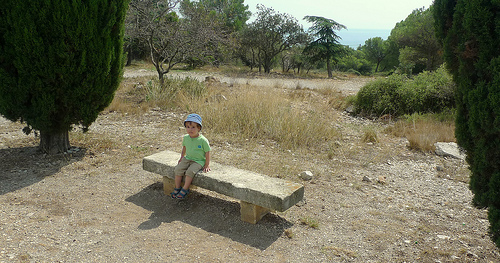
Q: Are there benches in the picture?
A: Yes, there is a bench.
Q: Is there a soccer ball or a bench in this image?
A: Yes, there is a bench.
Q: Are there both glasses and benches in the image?
A: No, there is a bench but no glasses.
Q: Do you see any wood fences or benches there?
A: Yes, there is a wood bench.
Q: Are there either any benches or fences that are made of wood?
A: Yes, the bench is made of wood.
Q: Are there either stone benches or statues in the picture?
A: Yes, there is a stone bench.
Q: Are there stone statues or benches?
A: Yes, there is a stone bench.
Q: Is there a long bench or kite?
A: Yes, there is a long bench.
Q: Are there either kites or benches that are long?
A: Yes, the bench is long.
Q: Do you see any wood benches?
A: Yes, there is a wood bench.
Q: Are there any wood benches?
A: Yes, there is a wood bench.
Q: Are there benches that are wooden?
A: Yes, there is a bench that is wooden.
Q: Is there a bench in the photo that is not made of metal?
A: Yes, there is a bench that is made of wood.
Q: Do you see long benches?
A: Yes, there is a long bench.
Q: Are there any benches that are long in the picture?
A: Yes, there is a long bench.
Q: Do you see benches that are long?
A: Yes, there is a bench that is long.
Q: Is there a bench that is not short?
A: Yes, there is a long bench.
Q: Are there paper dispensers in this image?
A: No, there are no paper dispensers.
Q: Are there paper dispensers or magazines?
A: No, there are no paper dispensers or magazines.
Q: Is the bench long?
A: Yes, the bench is long.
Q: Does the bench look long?
A: Yes, the bench is long.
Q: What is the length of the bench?
A: The bench is long.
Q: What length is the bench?
A: The bench is long.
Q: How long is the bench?
A: The bench is long.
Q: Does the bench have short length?
A: No, the bench is long.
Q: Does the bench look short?
A: No, the bench is long.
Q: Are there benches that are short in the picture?
A: No, there is a bench but it is long.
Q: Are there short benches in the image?
A: No, there is a bench but it is long.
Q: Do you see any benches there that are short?
A: No, there is a bench but it is long.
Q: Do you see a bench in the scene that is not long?
A: No, there is a bench but it is long.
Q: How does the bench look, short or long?
A: The bench is long.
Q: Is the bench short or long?
A: The bench is long.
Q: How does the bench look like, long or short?
A: The bench is long.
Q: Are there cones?
A: No, there are no cones.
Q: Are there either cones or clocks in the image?
A: No, there are no cones or clocks.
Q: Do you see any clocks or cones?
A: No, there are no cones or clocks.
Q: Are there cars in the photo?
A: No, there are no cars.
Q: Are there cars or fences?
A: No, there are no cars or fences.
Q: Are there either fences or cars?
A: No, there are no cars or fences.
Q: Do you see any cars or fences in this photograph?
A: No, there are no cars or fences.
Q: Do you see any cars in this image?
A: No, there are no cars.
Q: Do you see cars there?
A: No, there are no cars.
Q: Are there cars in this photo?
A: No, there are no cars.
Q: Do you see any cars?
A: No, there are no cars.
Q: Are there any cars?
A: No, there are no cars.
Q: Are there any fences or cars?
A: No, there are no cars or fences.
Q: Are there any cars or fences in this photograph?
A: No, there are no cars or fences.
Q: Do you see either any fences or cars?
A: No, there are no cars or fences.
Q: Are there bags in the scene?
A: No, there are no bags.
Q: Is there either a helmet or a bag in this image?
A: No, there are no bags or helmets.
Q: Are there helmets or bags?
A: No, there are no bags or helmets.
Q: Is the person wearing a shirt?
A: Yes, the person is wearing a shirt.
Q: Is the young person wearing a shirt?
A: Yes, the person is wearing a shirt.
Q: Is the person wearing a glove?
A: No, the person is wearing a shirt.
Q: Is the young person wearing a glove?
A: No, the person is wearing a shirt.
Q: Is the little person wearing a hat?
A: Yes, the person is wearing a hat.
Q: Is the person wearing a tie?
A: No, the person is wearing a hat.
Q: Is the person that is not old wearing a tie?
A: No, the person is wearing a hat.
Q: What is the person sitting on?
A: The person is sitting on the bench.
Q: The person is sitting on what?
A: The person is sitting on the bench.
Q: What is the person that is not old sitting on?
A: The person is sitting on the bench.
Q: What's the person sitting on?
A: The person is sitting on the bench.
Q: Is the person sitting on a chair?
A: No, the person is sitting on the bench.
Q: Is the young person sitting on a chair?
A: No, the person is sitting on the bench.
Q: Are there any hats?
A: Yes, there is a hat.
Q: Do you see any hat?
A: Yes, there is a hat.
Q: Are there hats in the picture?
A: Yes, there is a hat.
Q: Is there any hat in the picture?
A: Yes, there is a hat.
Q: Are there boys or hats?
A: Yes, there is a hat.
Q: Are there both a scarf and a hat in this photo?
A: No, there is a hat but no scarves.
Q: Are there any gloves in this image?
A: No, there are no gloves.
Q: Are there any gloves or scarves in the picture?
A: No, there are no gloves or scarves.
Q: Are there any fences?
A: No, there are no fences.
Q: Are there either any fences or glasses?
A: No, there are no fences or glasses.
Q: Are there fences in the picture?
A: No, there are no fences.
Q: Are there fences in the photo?
A: No, there are no fences.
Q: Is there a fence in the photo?
A: No, there are no fences.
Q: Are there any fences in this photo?
A: No, there are no fences.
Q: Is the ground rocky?
A: Yes, the ground is rocky.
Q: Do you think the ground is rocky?
A: Yes, the ground is rocky.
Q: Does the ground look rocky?
A: Yes, the ground is rocky.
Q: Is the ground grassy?
A: No, the ground is rocky.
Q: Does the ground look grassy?
A: No, the ground is rocky.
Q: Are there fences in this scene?
A: No, there are no fences.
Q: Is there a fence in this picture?
A: No, there are no fences.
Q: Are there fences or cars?
A: No, there are no fences or cars.